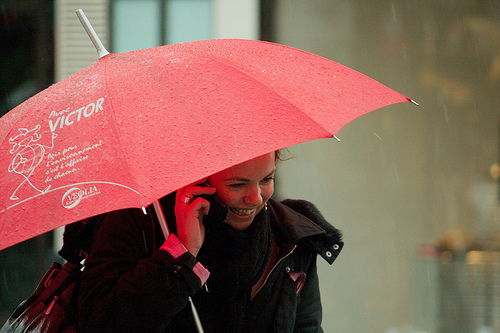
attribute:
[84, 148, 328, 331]
woman — smiling, walking in rain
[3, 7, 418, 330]
umbrella — red, wet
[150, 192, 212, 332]
handle — silver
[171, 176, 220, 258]
hand — right hand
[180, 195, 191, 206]
ring — silver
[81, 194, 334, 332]
jacket — black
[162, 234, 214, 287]
cuff — pink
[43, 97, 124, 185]
lettering — silver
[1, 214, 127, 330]
handbag — black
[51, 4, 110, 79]
shutter — white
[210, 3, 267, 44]
shutter — blurry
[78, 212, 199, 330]
sleeve — black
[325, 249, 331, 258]
snap — metal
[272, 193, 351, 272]
hood — black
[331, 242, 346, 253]
snap — silver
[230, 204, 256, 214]
teeth — white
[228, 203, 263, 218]
mouth — pink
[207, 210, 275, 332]
scarf — black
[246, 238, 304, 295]
zipper — metal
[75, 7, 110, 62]
top — silver